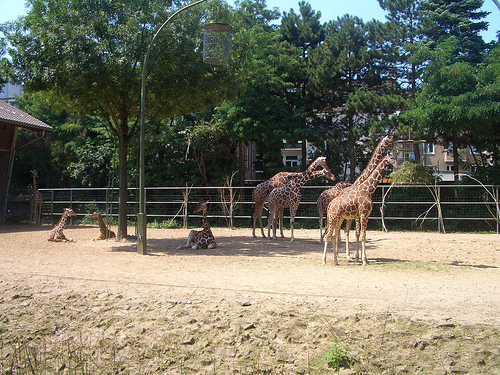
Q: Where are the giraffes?
A: In a pen.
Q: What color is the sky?
A: Blue.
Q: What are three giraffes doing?
A: Lying down.